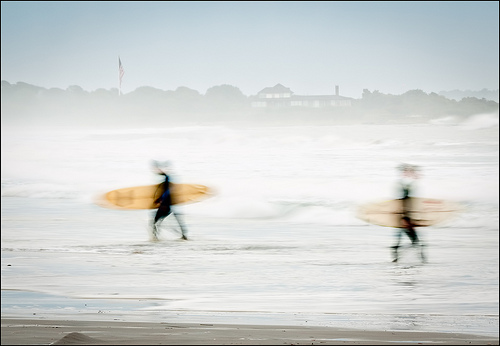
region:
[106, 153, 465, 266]
Two people with surfboard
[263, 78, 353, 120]
Buildings near the sea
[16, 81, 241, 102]
Lot of trees near the sea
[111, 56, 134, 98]
A flag with metal post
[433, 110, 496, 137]
Waves in the sea water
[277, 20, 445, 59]
A blue color sky with clouds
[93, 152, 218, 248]
A person walking with surfboard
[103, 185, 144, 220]
Light yellow color of the surfboard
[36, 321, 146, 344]
Wet sand near the sea water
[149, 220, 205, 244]
Legs of the person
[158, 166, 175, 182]
the head of a person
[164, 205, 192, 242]
the leg of a person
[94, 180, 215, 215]
a yellow surfboard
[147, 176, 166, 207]
the arm of a person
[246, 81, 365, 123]
a building on the beach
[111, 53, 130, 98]
a gray flag pole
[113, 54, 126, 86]
a flag on the pole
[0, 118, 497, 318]
water on the shore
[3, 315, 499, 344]
a brown sandy beach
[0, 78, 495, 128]
rocky bluffs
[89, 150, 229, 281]
This is a person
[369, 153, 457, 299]
This is a person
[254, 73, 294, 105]
This is a building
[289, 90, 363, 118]
This is a building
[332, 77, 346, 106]
This is a chimney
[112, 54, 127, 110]
This is a flag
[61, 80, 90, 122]
This is a tree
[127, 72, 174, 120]
This is a tree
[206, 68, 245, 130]
This is a tree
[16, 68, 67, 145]
This is a tree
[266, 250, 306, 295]
part of a shore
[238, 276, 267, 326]
edge of a shore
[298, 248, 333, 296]
part fo a water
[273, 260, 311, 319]
part of a shpore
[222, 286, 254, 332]
edge of a shore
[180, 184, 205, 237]
part of a board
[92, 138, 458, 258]
two surfers walking in ocean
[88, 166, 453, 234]
two surfboards being carried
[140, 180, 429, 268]
black wetsuits of surfers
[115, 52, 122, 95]
flag on flagpole in background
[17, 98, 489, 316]
ocean waters on beach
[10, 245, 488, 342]
sand of the beach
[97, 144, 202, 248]
surfer on left side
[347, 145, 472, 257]
surfer on right side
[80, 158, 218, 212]
yellow surfboard being carried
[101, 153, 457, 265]
two surfers on beach